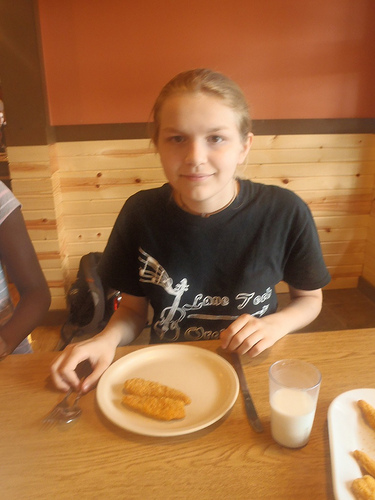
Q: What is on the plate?
A: Chicken.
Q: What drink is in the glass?
A: Milk.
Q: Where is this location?
A: Restaurant.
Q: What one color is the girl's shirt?
A: Black.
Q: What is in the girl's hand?
A: Silverware.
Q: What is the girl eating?
A: Chicken nuggets.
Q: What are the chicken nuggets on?
A: A plate.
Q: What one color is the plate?
A: White.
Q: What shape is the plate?
A: Circle.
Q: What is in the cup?
A: Milk.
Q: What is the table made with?
A: Wood.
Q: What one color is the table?
A: Brown.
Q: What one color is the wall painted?
A: Brown.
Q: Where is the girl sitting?
A: At table.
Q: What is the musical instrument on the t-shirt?
A: Violin.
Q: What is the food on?
A: Plate.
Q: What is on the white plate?
A: Chicken strips.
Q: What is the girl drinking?
A: Milk.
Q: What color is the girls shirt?
A: Black.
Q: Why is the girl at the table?
A: To eat.